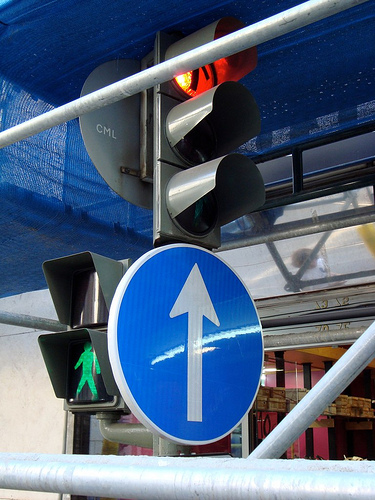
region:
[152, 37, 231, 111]
red light on pole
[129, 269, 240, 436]
blue and white sign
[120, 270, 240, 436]
white arrow on sign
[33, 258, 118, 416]
green pedestrian walk light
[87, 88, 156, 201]
circular sign behind red light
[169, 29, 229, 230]
grey housing for lights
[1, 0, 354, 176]
grey bar in front of red light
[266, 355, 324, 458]
red wall in distance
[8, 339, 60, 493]
white wall behind walk light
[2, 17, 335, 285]
blue tarp behind traffic lights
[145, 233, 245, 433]
A white arrow on blue sign.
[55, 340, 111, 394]
The crossing light is green.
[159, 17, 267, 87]
The traffic light is red.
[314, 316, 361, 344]
Numbers on the building.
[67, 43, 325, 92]
A iron pole by the traffic light.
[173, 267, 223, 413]
The arrow is white.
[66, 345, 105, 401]
The light is green.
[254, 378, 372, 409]
A wood piece inside store.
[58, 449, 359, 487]
The pole is iron.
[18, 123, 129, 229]
The canopy is blue.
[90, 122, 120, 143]
cml in white on sign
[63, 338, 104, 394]
green walk sign on signal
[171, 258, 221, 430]
white arrow on the sign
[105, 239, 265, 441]
blue sign on the pole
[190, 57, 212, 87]
arrow in the red light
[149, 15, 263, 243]
traffic signal on the pole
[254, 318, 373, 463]
grey pole on the street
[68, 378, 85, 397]
leg on green man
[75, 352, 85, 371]
arm on the green man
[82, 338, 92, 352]
the head on the green man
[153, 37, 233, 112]
traffic light is red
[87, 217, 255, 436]
blue and white sign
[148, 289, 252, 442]
white arrow on sign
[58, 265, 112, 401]
green pedestrian walk light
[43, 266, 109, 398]
black housing for lights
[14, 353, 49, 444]
white wall behind light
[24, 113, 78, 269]
blue tarp above lights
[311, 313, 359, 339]
tan numbers behind bars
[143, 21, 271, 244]
Traffic light showing red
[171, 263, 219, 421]
An arrow pointing up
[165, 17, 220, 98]
Red light glowing brightly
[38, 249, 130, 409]
A crosswalk signal showing "Walk"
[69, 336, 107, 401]
Illuminated image of a green man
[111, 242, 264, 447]
A circular blue sign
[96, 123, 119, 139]
Letters on the back of a sign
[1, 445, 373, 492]
A metal, horizontal pole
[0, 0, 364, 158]
A horizontal, metal pole